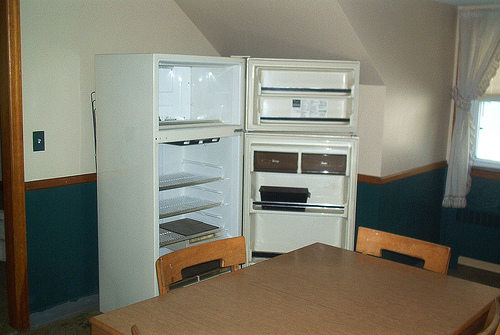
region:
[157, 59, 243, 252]
empty refrigerator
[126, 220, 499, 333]
four chairs at a table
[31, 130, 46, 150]
light switch on a white wall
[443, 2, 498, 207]
white curtains in a window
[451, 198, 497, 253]
green heating vents under a window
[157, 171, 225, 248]
three metal shelves in a refrigerator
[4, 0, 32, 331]
wooden door frame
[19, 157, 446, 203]
wooden chair rail along the walls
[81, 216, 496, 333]
table and chairs in front of a refrigerator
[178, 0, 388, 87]
white slanted section of ceiling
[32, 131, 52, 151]
light switch on the wall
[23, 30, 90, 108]
white painted portion of wall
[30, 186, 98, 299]
green painted part of wall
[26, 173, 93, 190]
wood grain on the wall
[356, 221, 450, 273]
wood chair at table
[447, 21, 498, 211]
white curtain over window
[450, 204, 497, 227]
vent on the wall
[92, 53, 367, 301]
white refridgerator in room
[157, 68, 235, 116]
inside of the freezer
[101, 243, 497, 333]
wooden table in room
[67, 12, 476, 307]
a fridge that is open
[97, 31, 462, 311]
a white fridge that is open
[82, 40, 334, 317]
a kitchen fridge that is open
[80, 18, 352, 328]
a fridge that is white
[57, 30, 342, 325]
a kitchen fridge that is white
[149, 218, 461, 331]
a table with chairs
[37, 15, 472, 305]
a fridge against the wall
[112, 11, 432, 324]
a fridge that is empty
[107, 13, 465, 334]
an open fridge against the wall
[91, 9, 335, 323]
a white fridge on the wall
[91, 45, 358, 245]
fridge is white colored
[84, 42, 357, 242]
fridge door is open and empty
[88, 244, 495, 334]
dark tan kitchen table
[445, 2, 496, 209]
white curtain on window side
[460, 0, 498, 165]
window with curtains on it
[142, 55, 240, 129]
freezer compartment is empty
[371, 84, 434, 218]
walls are white and dark blue with wooden sim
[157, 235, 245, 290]
wooden chair partially visible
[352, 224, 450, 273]
wooden chair partially visible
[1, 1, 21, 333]
doorway partially visible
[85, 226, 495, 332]
light grained wood laminate kitchen table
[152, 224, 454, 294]
two wooden kitchen chairs at a table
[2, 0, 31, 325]
brown stained wood door frame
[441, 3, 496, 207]
lacy white curtain on a kitchen window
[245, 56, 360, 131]
open freezer door to a refrigerator/freezer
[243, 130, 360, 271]
open refrigerator door to a refrigerator/freezer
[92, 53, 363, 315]
refrigerator/freezer with open doors in a kitchen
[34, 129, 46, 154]
wall light switch with a plate over it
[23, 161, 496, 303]
dark blue wainscoting with a wooden border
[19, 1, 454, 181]
white painted wall above wainscoting